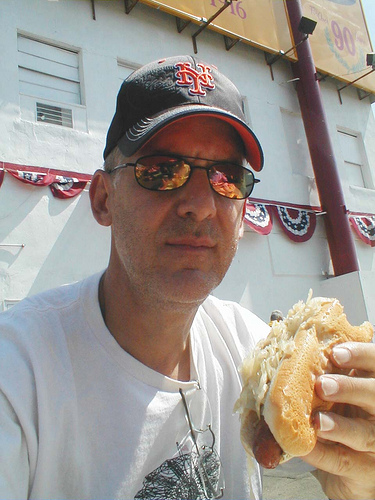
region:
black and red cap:
[103, 55, 266, 172]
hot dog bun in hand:
[240, 294, 372, 469]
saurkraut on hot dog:
[234, 289, 319, 421]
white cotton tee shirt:
[0, 267, 273, 499]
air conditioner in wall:
[35, 101, 73, 128]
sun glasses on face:
[109, 154, 261, 201]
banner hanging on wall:
[274, 204, 316, 242]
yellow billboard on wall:
[145, 1, 373, 95]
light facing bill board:
[281, 16, 318, 62]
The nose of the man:
[181, 173, 217, 219]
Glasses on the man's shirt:
[178, 387, 226, 499]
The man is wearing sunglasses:
[108, 154, 259, 200]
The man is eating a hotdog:
[234, 290, 372, 466]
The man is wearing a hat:
[102, 53, 262, 156]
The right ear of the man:
[90, 170, 111, 225]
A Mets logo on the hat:
[174, 61, 215, 97]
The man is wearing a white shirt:
[2, 269, 267, 498]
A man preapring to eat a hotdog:
[2, 56, 373, 499]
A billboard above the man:
[131, 0, 373, 103]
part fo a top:
[99, 413, 120, 440]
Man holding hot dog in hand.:
[232, 289, 369, 478]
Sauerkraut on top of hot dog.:
[228, 299, 322, 409]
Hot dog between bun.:
[252, 426, 286, 471]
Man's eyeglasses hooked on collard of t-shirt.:
[168, 374, 233, 498]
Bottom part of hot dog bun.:
[264, 303, 371, 456]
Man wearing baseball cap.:
[103, 51, 276, 172]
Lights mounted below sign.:
[271, 14, 373, 84]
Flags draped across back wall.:
[250, 192, 326, 245]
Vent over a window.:
[30, 96, 79, 133]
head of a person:
[58, 42, 293, 309]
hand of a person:
[272, 313, 367, 479]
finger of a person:
[288, 403, 365, 450]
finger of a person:
[312, 363, 370, 404]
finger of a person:
[326, 335, 373, 368]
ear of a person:
[75, 151, 122, 225]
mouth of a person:
[150, 228, 218, 260]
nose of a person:
[174, 181, 237, 221]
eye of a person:
[205, 155, 268, 211]